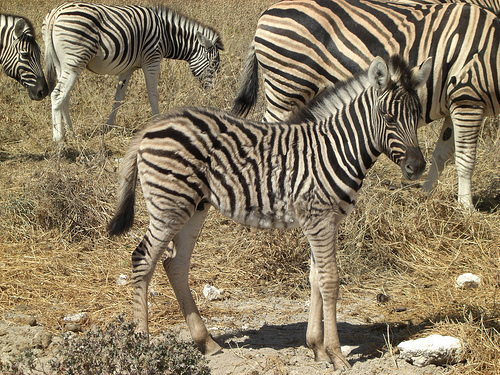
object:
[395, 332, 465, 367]
rock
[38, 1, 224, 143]
zebra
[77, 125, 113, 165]
grass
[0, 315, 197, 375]
shrubbery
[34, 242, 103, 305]
grass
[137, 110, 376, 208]
body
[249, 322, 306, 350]
shadow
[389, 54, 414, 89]
hair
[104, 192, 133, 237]
hair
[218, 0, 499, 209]
zebras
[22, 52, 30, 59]
eye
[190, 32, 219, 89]
head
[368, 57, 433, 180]
head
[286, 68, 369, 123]
mane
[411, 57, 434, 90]
ears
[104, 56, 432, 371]
zebra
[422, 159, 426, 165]
nose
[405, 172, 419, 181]
mouth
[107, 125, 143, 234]
tail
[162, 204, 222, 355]
legs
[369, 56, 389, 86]
ear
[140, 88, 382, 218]
stripes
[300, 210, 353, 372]
legs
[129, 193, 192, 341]
leg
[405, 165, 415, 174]
nose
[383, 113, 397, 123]
eye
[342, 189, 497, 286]
grass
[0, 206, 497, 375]
ground